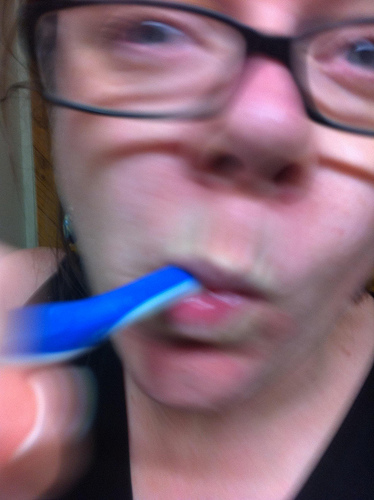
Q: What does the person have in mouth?
A: Toothbrush.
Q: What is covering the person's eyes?
A: Glasses.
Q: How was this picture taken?
A: Selfie.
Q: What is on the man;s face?
A: Glasses.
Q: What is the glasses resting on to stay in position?
A: Nose.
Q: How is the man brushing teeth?
A: With toothbrush.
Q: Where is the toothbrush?
A: In mouth.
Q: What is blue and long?
A: Toothbrush.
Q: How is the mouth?
A: Closed.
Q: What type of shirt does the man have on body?
A: V neck t shirt.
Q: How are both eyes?
A: Open.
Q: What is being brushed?
A: Teeth.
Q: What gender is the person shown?
A: Female.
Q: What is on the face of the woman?
A: Glasses.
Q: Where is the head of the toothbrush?
A: In the woman's mouth.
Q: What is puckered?
A: Woman's mouth.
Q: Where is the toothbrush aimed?
A: Down.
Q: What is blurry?
A: Picture.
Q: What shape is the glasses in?
A: Rectangular.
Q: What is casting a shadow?
A: Glasses.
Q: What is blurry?
A: The woman.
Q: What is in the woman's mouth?
A: A toothbrush.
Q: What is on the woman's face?
A: Glasses.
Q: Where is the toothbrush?
A: In the woman's mouth.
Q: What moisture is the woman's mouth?
A: Wet.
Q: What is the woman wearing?
A: A black shirt.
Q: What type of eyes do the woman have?
A: Blue eyes.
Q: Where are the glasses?
A: On the woman's face.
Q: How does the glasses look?
A: Black and slim.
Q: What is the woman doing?
A: Brushing her teeth.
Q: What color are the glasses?
A: Black.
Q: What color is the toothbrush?
A: Blue and white.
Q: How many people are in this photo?
A: One.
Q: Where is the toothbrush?
A: Person's mouth.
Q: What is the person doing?
A: Brushing teeth.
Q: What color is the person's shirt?
A: Black.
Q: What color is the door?
A: Brown.